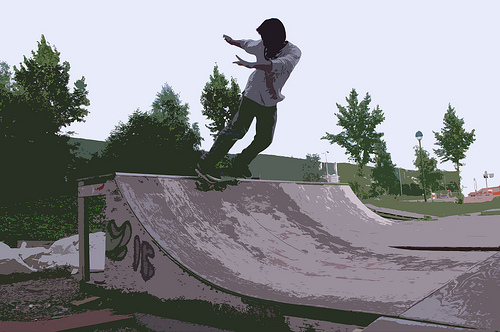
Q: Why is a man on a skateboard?
A: He is skateboarding.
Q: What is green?
A: Trees.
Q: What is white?
A: Man's shirt.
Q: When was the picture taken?
A: Daytime.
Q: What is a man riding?
A: A skateboard.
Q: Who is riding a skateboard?
A: A man.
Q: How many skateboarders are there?
A: One.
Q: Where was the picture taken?
A: At a skate park on a half pipe.